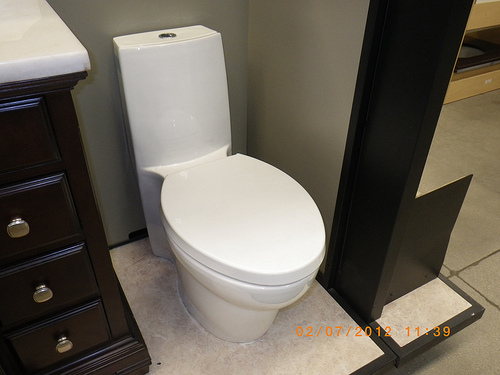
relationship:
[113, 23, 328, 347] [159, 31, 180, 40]
toilet has valve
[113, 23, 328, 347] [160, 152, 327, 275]
toilet has lid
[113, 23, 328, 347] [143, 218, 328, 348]
toilet has base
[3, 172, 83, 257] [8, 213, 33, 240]
drawer has handle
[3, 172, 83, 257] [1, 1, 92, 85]
drawer below counter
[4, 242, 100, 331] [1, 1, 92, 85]
drawer below counter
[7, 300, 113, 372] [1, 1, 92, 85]
drawer below counter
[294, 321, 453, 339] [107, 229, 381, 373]
date on floor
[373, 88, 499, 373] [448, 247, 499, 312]
floor has crack